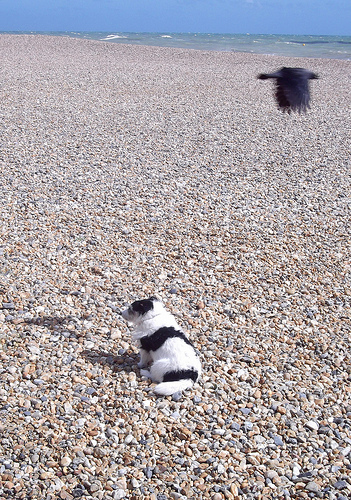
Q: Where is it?
A: This is at the beach.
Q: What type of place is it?
A: It is a beach.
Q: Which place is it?
A: It is a beach.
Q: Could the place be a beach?
A: Yes, it is a beach.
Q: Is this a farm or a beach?
A: It is a beach.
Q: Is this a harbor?
A: No, it is a beach.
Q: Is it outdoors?
A: Yes, it is outdoors.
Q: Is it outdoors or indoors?
A: It is outdoors.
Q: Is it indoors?
A: No, it is outdoors.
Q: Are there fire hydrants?
A: No, there are no fire hydrants.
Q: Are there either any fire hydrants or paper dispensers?
A: No, there are no fire hydrants or paper dispensers.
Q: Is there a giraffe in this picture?
A: No, there are no giraffes.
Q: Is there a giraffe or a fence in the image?
A: No, there are no giraffes or fences.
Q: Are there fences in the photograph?
A: No, there are no fences.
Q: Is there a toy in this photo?
A: No, there are no toys.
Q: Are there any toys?
A: No, there are no toys.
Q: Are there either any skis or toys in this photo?
A: No, there are no toys or skis.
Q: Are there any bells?
A: No, there are no bells.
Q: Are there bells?
A: No, there are no bells.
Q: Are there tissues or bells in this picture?
A: No, there are no bells or tissues.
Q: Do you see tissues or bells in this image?
A: No, there are no bells or tissues.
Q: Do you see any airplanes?
A: No, there are no airplanes.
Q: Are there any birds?
A: Yes, there is a bird.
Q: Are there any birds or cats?
A: Yes, there is a bird.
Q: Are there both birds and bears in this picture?
A: No, there is a bird but no bears.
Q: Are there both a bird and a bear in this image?
A: No, there is a bird but no bears.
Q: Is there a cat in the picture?
A: No, there are no cats.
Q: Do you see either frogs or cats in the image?
A: No, there are no cats or frogs.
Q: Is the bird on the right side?
A: Yes, the bird is on the right of the image.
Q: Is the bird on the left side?
A: No, the bird is on the right of the image.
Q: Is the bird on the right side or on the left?
A: The bird is on the right of the image.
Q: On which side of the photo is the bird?
A: The bird is on the right of the image.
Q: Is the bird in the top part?
A: Yes, the bird is in the top of the image.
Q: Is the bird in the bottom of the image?
A: No, the bird is in the top of the image.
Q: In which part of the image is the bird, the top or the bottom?
A: The bird is in the top of the image.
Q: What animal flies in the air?
A: The bird flies in the air.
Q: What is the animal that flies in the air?
A: The animal is a bird.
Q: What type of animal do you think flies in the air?
A: The animal is a bird.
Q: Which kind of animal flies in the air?
A: The animal is a bird.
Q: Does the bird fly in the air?
A: Yes, the bird flies in the air.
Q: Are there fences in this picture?
A: No, there are no fences.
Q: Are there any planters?
A: No, there are no planters.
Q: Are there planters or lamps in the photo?
A: No, there are no planters or lamps.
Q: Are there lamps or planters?
A: No, there are no planters or lamps.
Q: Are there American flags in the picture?
A: No, there are no American flags.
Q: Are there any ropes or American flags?
A: No, there are no American flags or ropes.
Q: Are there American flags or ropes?
A: No, there are no American flags or ropes.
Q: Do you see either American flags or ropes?
A: No, there are no American flags or ropes.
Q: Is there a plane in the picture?
A: No, there are no airplanes.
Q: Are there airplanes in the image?
A: No, there are no airplanes.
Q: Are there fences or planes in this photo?
A: No, there are no planes or fences.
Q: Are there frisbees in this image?
A: No, there are no frisbees.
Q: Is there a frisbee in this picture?
A: No, there are no frisbees.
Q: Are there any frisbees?
A: No, there are no frisbees.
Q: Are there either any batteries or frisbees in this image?
A: No, there are no frisbees or batteries.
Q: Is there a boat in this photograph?
A: No, there are no boats.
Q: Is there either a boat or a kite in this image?
A: No, there are no boats or kites.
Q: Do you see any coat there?
A: Yes, there is a coat.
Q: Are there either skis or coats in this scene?
A: Yes, there is a coat.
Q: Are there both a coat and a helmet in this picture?
A: No, there is a coat but no helmets.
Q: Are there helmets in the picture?
A: No, there are no helmets.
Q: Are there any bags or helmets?
A: No, there are no helmets or bags.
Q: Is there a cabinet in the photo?
A: No, there are no cabinets.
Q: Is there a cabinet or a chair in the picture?
A: No, there are no cabinets or chairs.